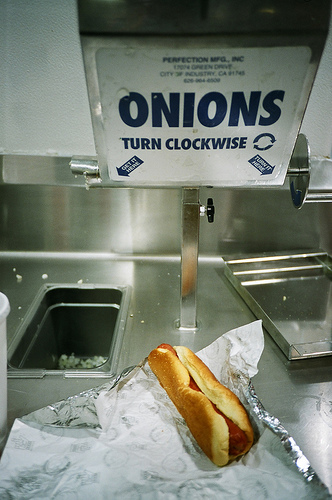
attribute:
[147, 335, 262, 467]
hotdog — cooked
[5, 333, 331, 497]
counter — metal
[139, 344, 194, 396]
bun — yellow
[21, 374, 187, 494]
paper — white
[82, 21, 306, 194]
sign — white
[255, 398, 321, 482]
foil — silver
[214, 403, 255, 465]
sausage — red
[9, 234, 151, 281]
surface — shiny, metallic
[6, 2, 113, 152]
wall — white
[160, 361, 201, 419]
bread — brown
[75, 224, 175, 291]
metal — silver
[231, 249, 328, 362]
tray — plastic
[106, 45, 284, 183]
text — blue